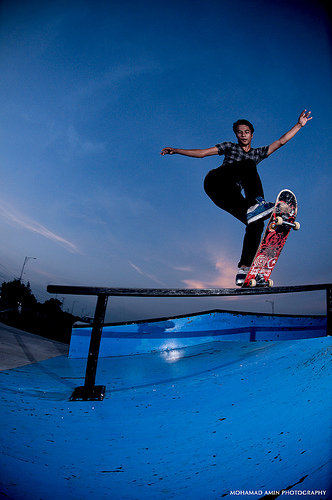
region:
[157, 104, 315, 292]
A guy is skateboarding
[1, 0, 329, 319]
White clouds in blue sky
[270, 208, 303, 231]
Two wheels on a skateboard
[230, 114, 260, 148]
Black hair on guy's head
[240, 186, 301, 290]
A red and black skateboard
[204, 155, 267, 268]
A pair of black pants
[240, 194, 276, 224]
A blue and white sneaker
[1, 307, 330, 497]
A blue skateboard ramp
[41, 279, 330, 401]
A black skateboard railing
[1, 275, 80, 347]
Trees are in the background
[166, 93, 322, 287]
person doing skateboard trick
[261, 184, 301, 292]
red skateboard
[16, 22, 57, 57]
white clouds in blue sky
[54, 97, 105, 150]
white clouds in blue sky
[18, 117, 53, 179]
white clouds in blue sky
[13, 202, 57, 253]
white clouds in blue sky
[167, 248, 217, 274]
white clouds in blue sky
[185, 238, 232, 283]
white clouds in blue sky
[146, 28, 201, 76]
white clouds in blue sky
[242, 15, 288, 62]
white clouds in blue sky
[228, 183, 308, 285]
RED SKATEBOARD UNDER FEET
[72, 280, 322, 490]
BLUE RAMP BELOW SKATER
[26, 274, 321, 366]
BLACK METAL RAIL ON RAMP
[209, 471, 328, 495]
COPYRIGHT ON BOTTOM RIGHT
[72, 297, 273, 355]
SHADOW OF RAIL ON RAMP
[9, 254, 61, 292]
STREET LIGHT IN BACKGROUND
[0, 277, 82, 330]
TREES GROWING IN BACKGROUND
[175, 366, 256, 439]
SMALL SCUFFS ON BLUE RAMP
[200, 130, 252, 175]
PLAID SHIRT ON SKATER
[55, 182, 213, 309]
WHITE CLOUDS IN SKY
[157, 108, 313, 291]
a male skateboarder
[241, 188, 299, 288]
A red and black skate board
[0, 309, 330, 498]
A skateboard ramp.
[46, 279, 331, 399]
A black, metal railing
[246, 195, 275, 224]
A blue and white gym shoe.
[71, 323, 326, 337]
Shadow of railing on the wall.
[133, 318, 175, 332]
Shadow of skateboarder on the wall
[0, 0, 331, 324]
Blue sky above skate park.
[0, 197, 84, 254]
Whispy, white clouds in sky.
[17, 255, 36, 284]
A light pole in the distance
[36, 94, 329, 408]
a skater on a ramp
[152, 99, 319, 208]
skater has extended arms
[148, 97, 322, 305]
skater wears black pants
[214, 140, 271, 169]
a squared gray and black top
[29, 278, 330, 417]
a black ramp for skating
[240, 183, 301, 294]
skateboard is red, white and black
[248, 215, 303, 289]
wheel of skater are white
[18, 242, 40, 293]
a streep pole on the background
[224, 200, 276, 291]
blue shoes with white soles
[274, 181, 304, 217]
nose of skateboard id black